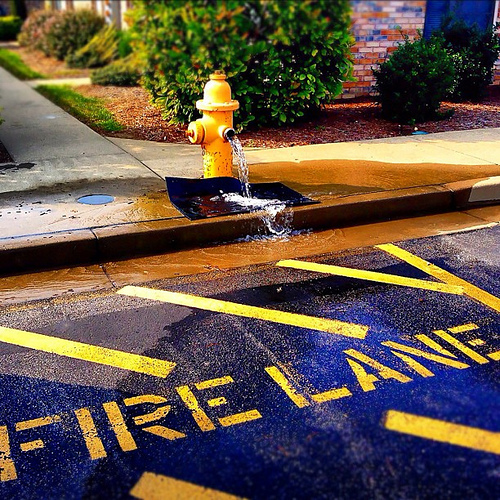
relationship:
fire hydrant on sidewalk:
[190, 69, 243, 184] [0, 120, 496, 275]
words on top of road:
[0, 318, 499, 489] [2, 201, 470, 488]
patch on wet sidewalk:
[58, 176, 340, 241] [307, 154, 412, 216]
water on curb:
[206, 133, 367, 288] [3, 162, 498, 278]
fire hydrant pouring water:
[190, 69, 243, 199] [206, 133, 367, 288]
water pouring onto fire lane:
[206, 133, 367, 288] [7, 310, 479, 478]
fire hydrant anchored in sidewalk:
[190, 69, 243, 199] [19, 159, 446, 217]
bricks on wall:
[344, 14, 421, 100] [330, 8, 471, 143]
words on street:
[0, 318, 499, 489] [2, 204, 499, 499]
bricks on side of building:
[358, 45, 373, 52] [32, 5, 427, 106]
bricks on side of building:
[344, 14, 421, 100] [32, 5, 427, 106]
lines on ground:
[0, 233, 499, 497] [0, 201, 499, 499]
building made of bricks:
[32, 5, 427, 106] [344, 58, 384, 72]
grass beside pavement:
[37, 70, 129, 138] [2, 67, 82, 157]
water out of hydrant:
[229, 133, 252, 188] [187, 67, 243, 176]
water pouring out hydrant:
[206, 133, 367, 288] [186, 72, 268, 211]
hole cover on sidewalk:
[66, 190, 115, 210] [0, 120, 496, 275]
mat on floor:
[161, 174, 321, 221] [178, 177, 307, 203]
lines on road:
[0, 241, 499, 498] [0, 217, 496, 496]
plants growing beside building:
[0, 1, 147, 91] [17, 0, 499, 120]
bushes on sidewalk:
[18, 7, 137, 87] [1, 57, 498, 277]